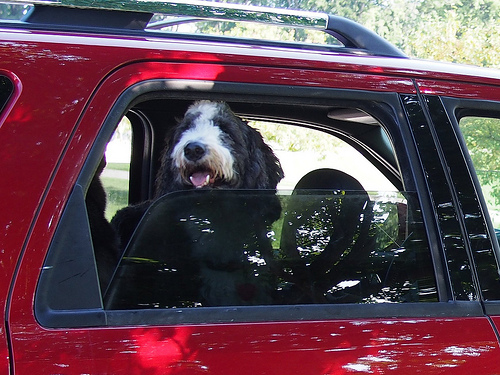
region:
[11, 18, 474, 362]
black and white dog looking out of car window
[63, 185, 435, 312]
partially rolled down car window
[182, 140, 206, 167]
shiny black dog nose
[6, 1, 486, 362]
side of red car carrying dog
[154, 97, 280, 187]
black and white dog head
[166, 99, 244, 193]
long haired dog with mouth open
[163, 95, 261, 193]
panting medium sized dog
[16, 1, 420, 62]
shiny roof rack on red car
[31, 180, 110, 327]
black triangular piece of car back window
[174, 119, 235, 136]
two eyes of long haired dog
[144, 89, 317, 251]
dog in car window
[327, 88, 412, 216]
partially open car window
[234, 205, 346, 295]
reflection on car window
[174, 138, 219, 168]
black nose on dog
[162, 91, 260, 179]
black and white fur on dog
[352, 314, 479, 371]
reflection on red door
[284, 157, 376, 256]
head rest of car seat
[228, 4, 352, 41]
rack on top of vehicle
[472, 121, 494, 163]
green leaves on tree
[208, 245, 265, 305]
tag on dog collar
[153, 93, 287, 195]
A dog peeking out a vehicle window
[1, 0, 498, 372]
A large Red Vehicle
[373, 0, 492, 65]
Green Vegetation the background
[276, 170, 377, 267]
The Passenger Headrest seen through a car window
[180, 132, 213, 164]
A Dark wet dog nose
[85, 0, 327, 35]
Silver and black bike railing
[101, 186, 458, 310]
Half Down Vehicle window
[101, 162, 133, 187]
Sidewalk or trail seen through a two car windows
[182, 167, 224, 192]
Dog's Tongue sitting in a dog mouth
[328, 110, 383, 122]
Grey Window Drop Shade in vehicle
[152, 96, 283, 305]
a black and white dog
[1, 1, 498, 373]
black and white dog inside a red SUV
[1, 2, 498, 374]
a dog sitting inside a red vehicle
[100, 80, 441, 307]
black and white dog looking out the vehicle's window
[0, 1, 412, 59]
a black rack on top of the red SUV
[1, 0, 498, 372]
a red SUV with the back window partially down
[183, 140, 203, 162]
a black nose on the dog's face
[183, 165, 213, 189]
two teeth inside the dog's mouth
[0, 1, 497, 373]
a dog standing on the back seat of SUV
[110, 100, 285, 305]
a dog standing in a SUV in the summertime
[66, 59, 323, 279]
a dog in the window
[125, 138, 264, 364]
a dog in the window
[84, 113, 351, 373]
a dog in the window